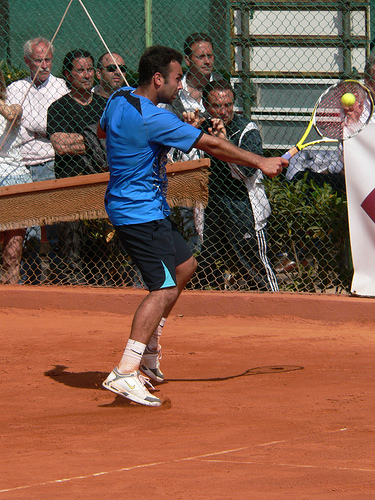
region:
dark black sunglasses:
[100, 61, 128, 73]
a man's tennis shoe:
[100, 366, 164, 408]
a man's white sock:
[117, 337, 147, 376]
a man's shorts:
[104, 208, 197, 291]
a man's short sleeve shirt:
[90, 90, 204, 232]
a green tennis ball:
[341, 93, 356, 106]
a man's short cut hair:
[135, 41, 182, 88]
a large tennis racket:
[277, 80, 373, 174]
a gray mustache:
[35, 65, 53, 72]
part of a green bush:
[253, 176, 343, 230]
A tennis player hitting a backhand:
[92, 42, 373, 410]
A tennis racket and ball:
[283, 78, 374, 159]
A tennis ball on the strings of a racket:
[321, 86, 368, 136]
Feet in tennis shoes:
[99, 339, 170, 411]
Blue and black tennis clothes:
[92, 83, 209, 294]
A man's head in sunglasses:
[92, 49, 130, 92]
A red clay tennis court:
[0, 279, 373, 498]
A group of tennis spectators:
[2, 29, 284, 294]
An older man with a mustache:
[18, 34, 58, 84]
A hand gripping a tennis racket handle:
[259, 142, 303, 181]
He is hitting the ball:
[290, 76, 365, 149]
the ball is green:
[335, 86, 352, 105]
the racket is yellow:
[285, 70, 370, 149]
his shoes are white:
[75, 344, 175, 418]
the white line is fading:
[124, 418, 344, 490]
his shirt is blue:
[93, 106, 196, 181]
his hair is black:
[146, 41, 182, 65]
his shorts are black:
[132, 211, 189, 266]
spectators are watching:
[0, 37, 273, 189]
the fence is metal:
[14, 18, 322, 255]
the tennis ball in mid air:
[341, 92, 354, 107]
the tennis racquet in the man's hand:
[260, 78, 373, 177]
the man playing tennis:
[96, 44, 372, 406]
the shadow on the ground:
[43, 364, 304, 407]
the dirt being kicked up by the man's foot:
[89, 364, 172, 414]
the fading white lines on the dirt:
[0, 426, 374, 499]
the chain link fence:
[0, 0, 373, 296]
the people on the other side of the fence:
[0, 31, 279, 290]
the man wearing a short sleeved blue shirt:
[95, 45, 288, 407]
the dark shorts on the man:
[112, 215, 192, 292]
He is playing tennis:
[255, 63, 362, 201]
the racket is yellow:
[267, 87, 344, 168]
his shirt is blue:
[119, 127, 149, 191]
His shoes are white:
[112, 362, 161, 407]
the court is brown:
[89, 302, 342, 477]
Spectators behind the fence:
[13, 47, 235, 148]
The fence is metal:
[0, 18, 312, 230]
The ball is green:
[326, 88, 370, 117]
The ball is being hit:
[257, 75, 367, 201]